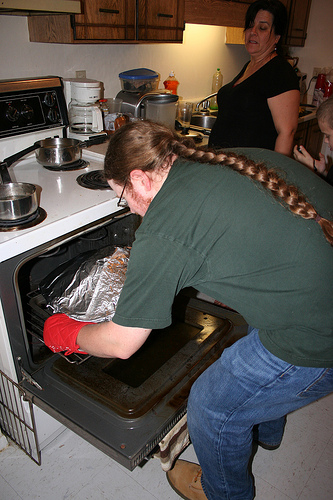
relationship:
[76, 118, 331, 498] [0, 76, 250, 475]
man pulling pan out of stove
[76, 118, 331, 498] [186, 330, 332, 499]
man wearing blue jeans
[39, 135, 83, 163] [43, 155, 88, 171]
pot on burner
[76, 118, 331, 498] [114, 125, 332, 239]
man has long hair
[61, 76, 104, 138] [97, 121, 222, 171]
coffee maker on counter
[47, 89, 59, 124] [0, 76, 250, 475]
knobs on stove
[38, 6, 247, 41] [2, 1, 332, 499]
cabinets in kitchen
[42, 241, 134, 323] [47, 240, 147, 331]
aluminum foil covering food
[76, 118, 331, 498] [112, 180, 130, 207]
man wearing glasses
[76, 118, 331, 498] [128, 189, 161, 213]
man has a beard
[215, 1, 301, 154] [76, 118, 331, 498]
woman standing behind man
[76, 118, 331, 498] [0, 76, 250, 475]
man pulling pan from stove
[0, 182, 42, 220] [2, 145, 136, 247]
saucepan on stove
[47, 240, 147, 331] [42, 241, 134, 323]
pan covered in aluminum foil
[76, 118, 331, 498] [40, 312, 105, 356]
man wearing an oven mitt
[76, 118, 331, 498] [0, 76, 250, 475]
man pulling food from stove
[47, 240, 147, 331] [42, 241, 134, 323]
food wrapped in aluminum foil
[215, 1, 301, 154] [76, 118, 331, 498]
woman watching man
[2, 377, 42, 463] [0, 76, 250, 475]
oven rack on side of stove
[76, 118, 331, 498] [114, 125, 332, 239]
man has a braid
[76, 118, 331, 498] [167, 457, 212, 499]
man wearing boots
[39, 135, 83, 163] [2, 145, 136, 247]
pan on stove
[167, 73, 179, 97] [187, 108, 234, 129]
dish soap by sink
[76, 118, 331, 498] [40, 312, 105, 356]
man wearing pot holder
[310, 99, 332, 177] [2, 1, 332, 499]
child in kitchen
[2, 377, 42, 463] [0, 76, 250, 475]
rack outside of stove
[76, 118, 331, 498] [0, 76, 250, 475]
man taking pan out of stove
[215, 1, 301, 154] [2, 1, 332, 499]
woman standing in kitchen